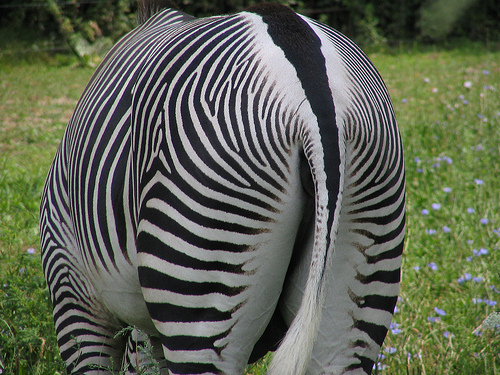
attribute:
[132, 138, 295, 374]
leg — striped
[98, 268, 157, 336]
underbelly — white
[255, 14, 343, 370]
stripe — one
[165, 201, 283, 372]
leg — zebras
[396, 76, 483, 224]
field — grass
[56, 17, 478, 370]
zebra — white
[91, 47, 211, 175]
stripes — black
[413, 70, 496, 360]
flowers — purple